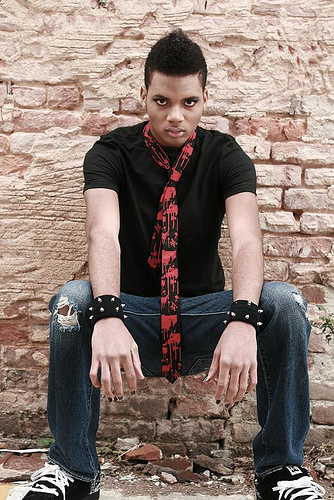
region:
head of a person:
[128, 17, 234, 155]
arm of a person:
[68, 191, 151, 312]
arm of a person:
[205, 184, 288, 319]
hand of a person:
[64, 317, 158, 398]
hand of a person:
[196, 318, 289, 401]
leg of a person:
[30, 324, 123, 450]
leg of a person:
[254, 331, 316, 426]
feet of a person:
[27, 455, 136, 497]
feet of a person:
[248, 463, 321, 498]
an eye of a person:
[145, 88, 178, 117]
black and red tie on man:
[148, 117, 207, 376]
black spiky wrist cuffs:
[78, 292, 130, 321]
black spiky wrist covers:
[228, 296, 264, 327]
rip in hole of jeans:
[44, 293, 80, 337]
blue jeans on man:
[44, 282, 88, 464]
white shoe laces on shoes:
[27, 464, 68, 483]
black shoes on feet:
[12, 470, 90, 498]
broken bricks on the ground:
[100, 429, 189, 480]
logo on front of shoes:
[277, 463, 305, 482]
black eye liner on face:
[179, 96, 201, 108]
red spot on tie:
[159, 360, 173, 373]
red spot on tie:
[160, 345, 169, 355]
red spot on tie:
[170, 342, 179, 359]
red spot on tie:
[163, 332, 181, 344]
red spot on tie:
[160, 312, 176, 330]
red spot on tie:
[160, 293, 169, 305]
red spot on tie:
[167, 298, 176, 314]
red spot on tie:
[158, 275, 166, 287]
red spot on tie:
[156, 245, 178, 268]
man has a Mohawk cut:
[100, 21, 237, 169]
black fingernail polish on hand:
[208, 283, 293, 436]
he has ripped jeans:
[22, 276, 154, 420]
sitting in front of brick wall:
[89, 31, 326, 444]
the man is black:
[41, 9, 301, 407]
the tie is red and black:
[148, 249, 231, 361]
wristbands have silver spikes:
[78, 281, 142, 361]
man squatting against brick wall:
[20, 30, 323, 498]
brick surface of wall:
[263, 144, 331, 273]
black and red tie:
[149, 122, 195, 382]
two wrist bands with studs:
[88, 294, 264, 330]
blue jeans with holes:
[47, 282, 313, 481]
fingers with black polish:
[89, 323, 143, 402]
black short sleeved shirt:
[84, 119, 256, 296]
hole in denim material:
[55, 295, 80, 330]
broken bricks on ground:
[101, 444, 257, 498]